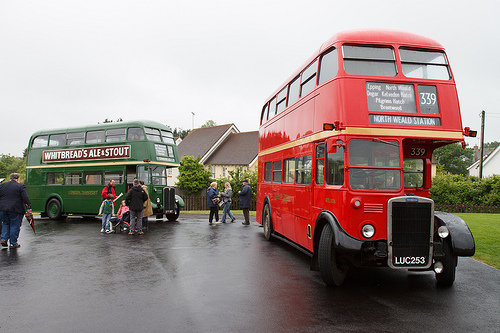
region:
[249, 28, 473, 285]
a double decker red bus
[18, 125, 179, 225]
a double decker green bus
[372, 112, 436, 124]
a bus destination sign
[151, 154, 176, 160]
a bus destination sign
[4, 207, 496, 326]
wet paved pavement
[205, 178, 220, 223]
a woman standing in street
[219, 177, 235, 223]
a woman standing in street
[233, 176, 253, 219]
a man standing in street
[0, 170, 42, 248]
a man standing in street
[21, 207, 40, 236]
a colorful umbrella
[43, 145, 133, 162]
the sign says Whitbread's Ale & Stout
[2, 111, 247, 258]
this is a double decker bus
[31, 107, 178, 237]
the bus is green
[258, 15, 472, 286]
this is another double decker bus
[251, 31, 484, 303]
the bus is red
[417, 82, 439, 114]
this bus has 339 on the front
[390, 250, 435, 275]
the license tag reads LUC253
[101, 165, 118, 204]
this man is in a red jacket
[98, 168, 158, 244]
a group of people are chatting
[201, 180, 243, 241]
these two ladies look like they are ready to fight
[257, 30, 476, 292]
large, double deck red bus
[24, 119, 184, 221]
green, double deck bus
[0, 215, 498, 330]
Black, wet ground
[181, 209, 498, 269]
green, manicured lawn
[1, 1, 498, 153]
Overcast, cloudy sky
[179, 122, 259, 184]
white house with brown roof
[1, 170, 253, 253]
group of people standing around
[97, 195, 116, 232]
little child in green vest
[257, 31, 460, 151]
Upper Deck of red bus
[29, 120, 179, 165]
upper deck of green bus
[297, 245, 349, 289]
part of a wheel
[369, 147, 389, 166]
part of a window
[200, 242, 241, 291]
part of a road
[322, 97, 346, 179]
part of a side mirror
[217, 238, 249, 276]
part of a mirror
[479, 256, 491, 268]
edge of a road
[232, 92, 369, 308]
the bus is red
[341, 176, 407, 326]
the bus is red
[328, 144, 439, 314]
the bus is red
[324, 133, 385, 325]
the bus is red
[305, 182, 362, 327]
the bus is red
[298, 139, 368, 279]
the bus is red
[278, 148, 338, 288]
the bus is red